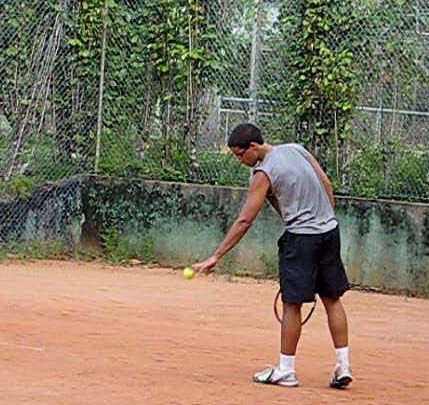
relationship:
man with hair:
[189, 122, 354, 389] [228, 122, 264, 152]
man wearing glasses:
[189, 122, 354, 389] [236, 146, 249, 162]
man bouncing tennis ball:
[189, 122, 354, 389] [184, 267, 195, 280]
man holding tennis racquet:
[189, 122, 354, 389] [274, 287, 317, 327]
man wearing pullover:
[189, 122, 354, 389] [252, 143, 340, 235]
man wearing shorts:
[189, 122, 354, 389] [278, 225, 351, 304]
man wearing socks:
[189, 122, 354, 389] [278, 346, 351, 372]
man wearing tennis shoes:
[189, 122, 354, 389] [252, 363, 355, 389]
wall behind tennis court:
[1, 172, 429, 301] [1, 256, 427, 404]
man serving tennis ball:
[189, 122, 354, 389] [184, 267, 195, 280]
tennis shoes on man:
[252, 363, 355, 389] [189, 122, 354, 389]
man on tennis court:
[189, 122, 354, 389] [1, 256, 427, 404]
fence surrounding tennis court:
[2, 2, 429, 248] [1, 256, 427, 404]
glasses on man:
[236, 146, 249, 162] [189, 122, 354, 389]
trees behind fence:
[261, 2, 428, 206] [2, 2, 429, 248]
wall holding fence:
[1, 172, 429, 301] [2, 2, 429, 248]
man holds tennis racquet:
[189, 122, 354, 389] [274, 287, 317, 327]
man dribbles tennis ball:
[189, 122, 354, 389] [184, 267, 195, 280]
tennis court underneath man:
[1, 256, 427, 404] [189, 122, 354, 389]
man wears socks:
[189, 122, 354, 389] [278, 346, 351, 372]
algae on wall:
[335, 197, 428, 300] [1, 172, 429, 301]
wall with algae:
[1, 172, 429, 301] [335, 197, 428, 300]